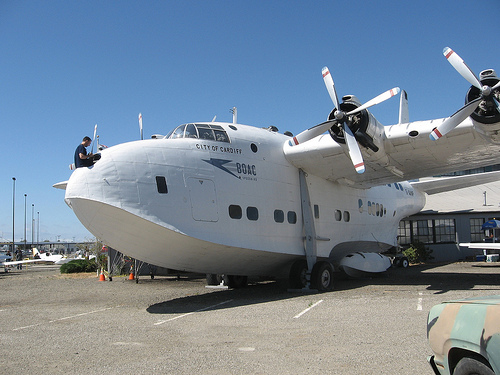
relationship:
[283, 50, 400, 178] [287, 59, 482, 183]
propeller on wing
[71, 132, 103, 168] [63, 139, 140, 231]
man on nose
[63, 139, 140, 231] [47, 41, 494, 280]
nose of plane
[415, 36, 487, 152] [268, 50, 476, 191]
propeller on wing wing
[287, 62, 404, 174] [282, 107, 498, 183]
propeller on wing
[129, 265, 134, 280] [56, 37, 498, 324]
traffic cone behind plane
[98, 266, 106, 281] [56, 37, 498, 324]
traffic cone behind plane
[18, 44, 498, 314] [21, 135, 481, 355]
plane at airport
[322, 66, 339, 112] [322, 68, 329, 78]
blade has red stripe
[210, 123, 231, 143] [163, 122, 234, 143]
window in cockpit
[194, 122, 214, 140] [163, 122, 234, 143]
window in cockpit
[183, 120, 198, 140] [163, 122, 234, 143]
window in cockpit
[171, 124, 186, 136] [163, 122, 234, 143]
window in cockpit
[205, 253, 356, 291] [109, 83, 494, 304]
wheels of plane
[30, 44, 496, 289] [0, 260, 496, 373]
airplane parked in a parking lot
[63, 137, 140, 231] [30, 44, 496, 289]
nose of airplane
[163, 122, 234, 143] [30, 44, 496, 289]
cockpit of airplane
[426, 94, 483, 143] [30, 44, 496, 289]
propeller on airplane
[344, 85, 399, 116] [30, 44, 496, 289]
propeller on airplane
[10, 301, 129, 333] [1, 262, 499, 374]
white line on pavement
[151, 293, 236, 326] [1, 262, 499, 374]
white line on pavement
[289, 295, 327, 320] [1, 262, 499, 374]
white line on pavement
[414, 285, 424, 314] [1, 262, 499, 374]
white line on pavement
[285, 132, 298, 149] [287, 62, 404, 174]
line on propeller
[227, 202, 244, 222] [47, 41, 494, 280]
window on plane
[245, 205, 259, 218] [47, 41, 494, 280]
window on plane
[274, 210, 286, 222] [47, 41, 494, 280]
window on plane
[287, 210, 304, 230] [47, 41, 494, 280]
window on plane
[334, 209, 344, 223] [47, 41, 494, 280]
window on plane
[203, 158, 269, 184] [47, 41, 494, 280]
label on plane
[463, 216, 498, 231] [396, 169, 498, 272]
umbrella in front of building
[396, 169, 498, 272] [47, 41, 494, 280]
building behind plane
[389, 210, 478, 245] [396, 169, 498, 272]
windows on building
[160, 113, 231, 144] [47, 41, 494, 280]
window on front of plane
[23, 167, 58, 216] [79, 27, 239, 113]
clouds in sky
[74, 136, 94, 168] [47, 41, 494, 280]
man sitting on plane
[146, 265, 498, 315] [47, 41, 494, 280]
shadow of plane